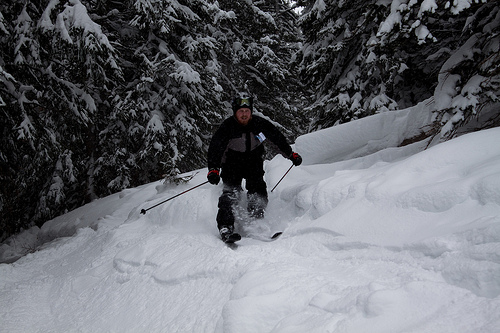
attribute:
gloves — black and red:
[202, 165, 224, 183]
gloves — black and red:
[285, 150, 304, 167]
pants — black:
[217, 165, 268, 232]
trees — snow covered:
[170, 7, 444, 117]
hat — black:
[231, 94, 253, 110]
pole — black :
[140, 180, 209, 214]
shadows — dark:
[235, 212, 293, 258]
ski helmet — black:
[237, 95, 252, 113]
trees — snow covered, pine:
[333, 22, 433, 77]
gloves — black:
[201, 145, 308, 194]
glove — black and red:
[203, 168, 225, 182]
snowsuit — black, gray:
[220, 119, 272, 218]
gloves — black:
[206, 167, 221, 187]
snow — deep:
[282, 176, 493, 330]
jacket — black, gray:
[208, 115, 291, 167]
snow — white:
[48, 126, 480, 320]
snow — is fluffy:
[296, 165, 488, 304]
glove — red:
[206, 168, 221, 184]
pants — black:
[211, 164, 269, 230]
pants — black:
[212, 153, 287, 242]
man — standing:
[206, 82, 318, 229]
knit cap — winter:
[215, 85, 271, 115]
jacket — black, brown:
[161, 114, 339, 224]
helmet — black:
[224, 90, 259, 111]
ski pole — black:
[138, 173, 213, 221]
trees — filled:
[4, 1, 494, 233]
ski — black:
[178, 224, 243, 251]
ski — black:
[220, 227, 243, 247]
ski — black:
[264, 227, 283, 238]